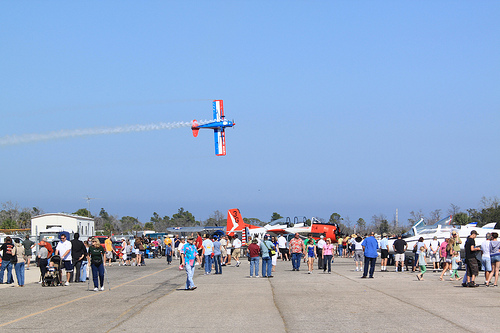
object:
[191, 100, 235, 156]
plane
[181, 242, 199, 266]
shirt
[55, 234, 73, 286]
man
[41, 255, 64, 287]
stroller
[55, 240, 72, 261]
shirt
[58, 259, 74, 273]
shorts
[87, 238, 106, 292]
woman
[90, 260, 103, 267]
fanny pack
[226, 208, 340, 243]
plane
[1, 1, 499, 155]
sky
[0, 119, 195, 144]
smoke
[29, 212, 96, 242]
hangar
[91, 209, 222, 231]
trees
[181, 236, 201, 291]
man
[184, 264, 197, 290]
jeans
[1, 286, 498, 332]
ground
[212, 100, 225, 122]
wing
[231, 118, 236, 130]
propeller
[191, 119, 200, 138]
tail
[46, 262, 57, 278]
child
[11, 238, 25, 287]
people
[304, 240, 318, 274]
woman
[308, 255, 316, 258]
shorts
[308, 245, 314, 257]
shirt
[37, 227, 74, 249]
bus